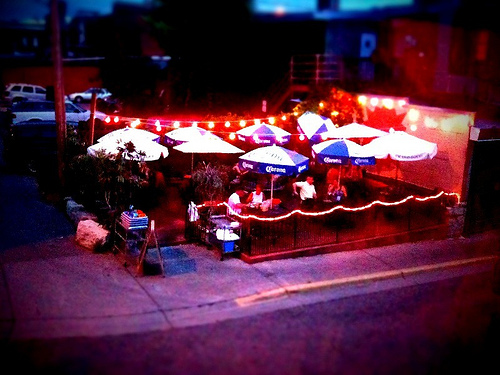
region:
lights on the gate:
[245, 197, 424, 212]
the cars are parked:
[10, 76, 106, 141]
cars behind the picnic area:
[15, 76, 330, 133]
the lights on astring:
[126, 116, 276, 129]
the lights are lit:
[353, 90, 433, 132]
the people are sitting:
[224, 174, 347, 209]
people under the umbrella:
[234, 147, 296, 217]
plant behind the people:
[192, 160, 277, 203]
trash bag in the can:
[213, 217, 243, 259]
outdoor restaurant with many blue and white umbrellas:
[86, 98, 436, 263]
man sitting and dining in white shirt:
[228, 196, 242, 208]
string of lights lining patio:
[97, 108, 293, 130]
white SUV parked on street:
[6, 79, 67, 104]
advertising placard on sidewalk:
[129, 215, 174, 282]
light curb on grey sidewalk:
[241, 250, 499, 302]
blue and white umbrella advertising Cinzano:
[313, 133, 375, 170]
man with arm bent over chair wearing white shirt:
[286, 180, 321, 201]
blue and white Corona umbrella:
[240, 142, 316, 182]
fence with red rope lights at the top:
[222, 199, 461, 256]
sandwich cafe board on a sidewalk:
[134, 217, 187, 277]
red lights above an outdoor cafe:
[81, 88, 485, 151]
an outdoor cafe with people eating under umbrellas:
[87, 115, 459, 240]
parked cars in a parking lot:
[4, 72, 126, 132]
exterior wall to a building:
[318, 95, 498, 203]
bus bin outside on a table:
[107, 196, 152, 256]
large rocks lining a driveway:
[57, 185, 107, 258]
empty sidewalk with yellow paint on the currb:
[230, 245, 498, 317]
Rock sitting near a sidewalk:
[75, 218, 110, 248]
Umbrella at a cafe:
[234, 141, 309, 176]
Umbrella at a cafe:
[307, 138, 372, 165]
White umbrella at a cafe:
[369, 130, 436, 161]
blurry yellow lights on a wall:
[414, 107, 476, 137]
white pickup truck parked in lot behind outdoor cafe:
[11, 96, 111, 135]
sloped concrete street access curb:
[48, 292, 316, 337]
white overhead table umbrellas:
[85, 134, 240, 161]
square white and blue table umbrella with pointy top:
[241, 145, 311, 175]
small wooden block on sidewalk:
[74, 217, 109, 252]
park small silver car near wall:
[68, 81, 112, 103]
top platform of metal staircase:
[287, 51, 340, 95]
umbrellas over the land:
[26, 89, 434, 249]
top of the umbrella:
[241, 133, 306, 172]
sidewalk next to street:
[192, 242, 415, 332]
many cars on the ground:
[6, 58, 125, 163]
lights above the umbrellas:
[128, 67, 462, 190]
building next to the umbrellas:
[259, 10, 481, 90]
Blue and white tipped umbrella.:
[295, 109, 337, 143]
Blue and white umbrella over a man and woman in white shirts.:
[237, 141, 309, 176]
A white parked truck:
[11, 100, 109, 126]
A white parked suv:
[3, 81, 48, 102]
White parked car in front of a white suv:
[67, 86, 112, 102]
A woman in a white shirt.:
[247, 184, 266, 204]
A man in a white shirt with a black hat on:
[225, 185, 251, 215]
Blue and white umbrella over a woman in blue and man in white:
[310, 138, 375, 165]